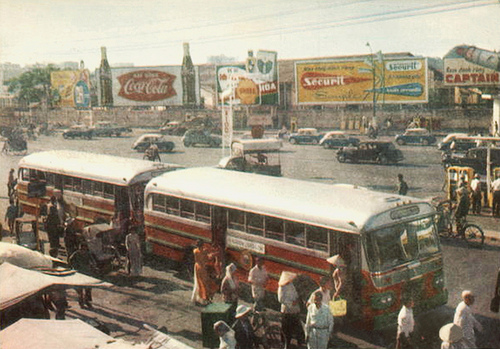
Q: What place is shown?
A: It is a parking lot.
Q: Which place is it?
A: It is a parking lot.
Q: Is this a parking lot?
A: Yes, it is a parking lot.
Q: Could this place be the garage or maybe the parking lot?
A: It is the parking lot.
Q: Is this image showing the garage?
A: No, the picture is showing the parking lot.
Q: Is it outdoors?
A: Yes, it is outdoors.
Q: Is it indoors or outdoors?
A: It is outdoors.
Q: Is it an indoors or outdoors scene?
A: It is outdoors.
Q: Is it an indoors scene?
A: No, it is outdoors.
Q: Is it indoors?
A: No, it is outdoors.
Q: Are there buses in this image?
A: Yes, there is a bus.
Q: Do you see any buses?
A: Yes, there is a bus.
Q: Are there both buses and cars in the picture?
A: Yes, there are both a bus and a car.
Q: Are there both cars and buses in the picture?
A: Yes, there are both a bus and a car.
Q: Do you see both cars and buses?
A: Yes, there are both a bus and a car.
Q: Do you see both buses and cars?
A: Yes, there are both a bus and a car.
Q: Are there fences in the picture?
A: No, there are no fences.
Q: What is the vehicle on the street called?
A: The vehicle is a bus.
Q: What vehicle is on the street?
A: The vehicle is a bus.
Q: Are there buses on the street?
A: Yes, there is a bus on the street.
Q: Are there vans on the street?
A: No, there is a bus on the street.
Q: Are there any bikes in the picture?
A: Yes, there is a bike.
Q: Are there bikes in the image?
A: Yes, there is a bike.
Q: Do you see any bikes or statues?
A: Yes, there is a bike.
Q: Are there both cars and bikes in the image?
A: Yes, there are both a bike and a car.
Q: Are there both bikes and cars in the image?
A: Yes, there are both a bike and a car.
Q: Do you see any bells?
A: No, there are no bells.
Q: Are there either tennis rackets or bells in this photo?
A: No, there are no bells or tennis rackets.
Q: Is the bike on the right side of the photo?
A: Yes, the bike is on the right of the image.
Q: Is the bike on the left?
A: No, the bike is on the right of the image.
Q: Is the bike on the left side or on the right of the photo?
A: The bike is on the right of the image.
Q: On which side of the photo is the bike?
A: The bike is on the right of the image.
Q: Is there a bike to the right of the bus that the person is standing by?
A: Yes, there is a bike to the right of the bus.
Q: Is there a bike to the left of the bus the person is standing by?
A: No, the bike is to the right of the bus.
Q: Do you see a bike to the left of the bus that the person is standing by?
A: No, the bike is to the right of the bus.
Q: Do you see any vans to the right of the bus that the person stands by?
A: No, there is a bike to the right of the bus.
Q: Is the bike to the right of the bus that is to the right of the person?
A: Yes, the bike is to the right of the bus.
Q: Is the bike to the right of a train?
A: No, the bike is to the right of the bus.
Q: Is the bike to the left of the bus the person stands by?
A: No, the bike is to the right of the bus.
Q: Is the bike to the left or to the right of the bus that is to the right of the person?
A: The bike is to the right of the bus.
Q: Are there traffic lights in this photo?
A: No, there are no traffic lights.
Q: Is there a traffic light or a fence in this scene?
A: No, there are no traffic lights or fences.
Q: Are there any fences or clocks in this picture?
A: No, there are no fences or clocks.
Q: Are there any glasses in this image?
A: No, there are no glasses.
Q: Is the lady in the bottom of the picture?
A: Yes, the lady is in the bottom of the image.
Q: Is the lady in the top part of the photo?
A: No, the lady is in the bottom of the image.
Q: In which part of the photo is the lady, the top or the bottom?
A: The lady is in the bottom of the image.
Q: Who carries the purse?
A: The lady carries the purse.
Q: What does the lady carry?
A: The lady carries a purse.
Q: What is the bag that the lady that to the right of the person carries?
A: The bag is a purse.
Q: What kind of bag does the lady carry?
A: The lady carries a purse.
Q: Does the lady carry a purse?
A: Yes, the lady carries a purse.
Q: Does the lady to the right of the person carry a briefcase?
A: No, the lady carries a purse.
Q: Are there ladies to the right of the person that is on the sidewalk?
A: Yes, there is a lady to the right of the person.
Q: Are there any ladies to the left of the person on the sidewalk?
A: No, the lady is to the right of the person.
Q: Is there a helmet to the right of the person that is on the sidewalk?
A: No, there is a lady to the right of the person.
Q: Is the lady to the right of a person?
A: Yes, the lady is to the right of a person.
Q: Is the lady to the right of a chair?
A: No, the lady is to the right of a person.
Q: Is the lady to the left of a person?
A: No, the lady is to the right of a person.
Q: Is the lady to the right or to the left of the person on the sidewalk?
A: The lady is to the right of the person.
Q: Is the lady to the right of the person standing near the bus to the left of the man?
A: Yes, the lady is standing near the bus.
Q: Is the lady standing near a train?
A: No, the lady is standing near the bus.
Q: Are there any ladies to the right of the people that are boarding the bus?
A: Yes, there is a lady to the right of the people.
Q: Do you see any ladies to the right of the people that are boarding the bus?
A: Yes, there is a lady to the right of the people.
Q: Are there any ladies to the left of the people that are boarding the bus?
A: No, the lady is to the right of the people.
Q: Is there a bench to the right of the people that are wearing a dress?
A: No, there is a lady to the right of the people.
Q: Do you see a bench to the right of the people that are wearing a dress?
A: No, there is a lady to the right of the people.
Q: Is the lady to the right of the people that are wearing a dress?
A: Yes, the lady is to the right of the people.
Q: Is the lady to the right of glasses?
A: No, the lady is to the right of the people.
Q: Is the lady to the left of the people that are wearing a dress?
A: No, the lady is to the right of the people.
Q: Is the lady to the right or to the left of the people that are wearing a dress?
A: The lady is to the right of the people.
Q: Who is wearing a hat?
A: The lady is wearing a hat.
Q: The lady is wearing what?
A: The lady is wearing a hat.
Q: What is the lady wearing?
A: The lady is wearing a hat.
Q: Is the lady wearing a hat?
A: Yes, the lady is wearing a hat.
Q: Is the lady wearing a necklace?
A: No, the lady is wearing a hat.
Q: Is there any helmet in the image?
A: No, there are no helmets.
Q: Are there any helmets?
A: No, there are no helmets.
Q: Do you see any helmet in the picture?
A: No, there are no helmets.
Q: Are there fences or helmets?
A: No, there are no helmets or fences.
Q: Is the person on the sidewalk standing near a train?
A: No, the person is standing near the bus.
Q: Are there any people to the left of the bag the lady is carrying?
A: Yes, there is a person to the left of the purse.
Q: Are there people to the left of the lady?
A: Yes, there is a person to the left of the lady.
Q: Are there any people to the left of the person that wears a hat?
A: Yes, there is a person to the left of the lady.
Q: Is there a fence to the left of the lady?
A: No, there is a person to the left of the lady.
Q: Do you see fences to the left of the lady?
A: No, there is a person to the left of the lady.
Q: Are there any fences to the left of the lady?
A: No, there is a person to the left of the lady.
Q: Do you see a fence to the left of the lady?
A: No, there is a person to the left of the lady.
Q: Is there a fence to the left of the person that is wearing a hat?
A: No, there is a person to the left of the lady.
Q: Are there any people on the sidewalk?
A: Yes, there is a person on the sidewalk.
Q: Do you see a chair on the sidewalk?
A: No, there is a person on the sidewalk.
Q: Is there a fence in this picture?
A: No, there are no fences.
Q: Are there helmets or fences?
A: No, there are no fences or helmets.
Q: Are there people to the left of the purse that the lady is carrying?
A: Yes, there is a person to the left of the purse.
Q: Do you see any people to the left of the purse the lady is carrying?
A: Yes, there is a person to the left of the purse.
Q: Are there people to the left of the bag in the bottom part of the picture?
A: Yes, there is a person to the left of the purse.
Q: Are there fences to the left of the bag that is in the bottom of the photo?
A: No, there is a person to the left of the purse.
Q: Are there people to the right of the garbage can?
A: Yes, there is a person to the right of the garbage can.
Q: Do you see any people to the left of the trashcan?
A: No, the person is to the right of the trashcan.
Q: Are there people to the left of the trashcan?
A: No, the person is to the right of the trashcan.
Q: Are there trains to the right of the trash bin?
A: No, there is a person to the right of the trash bin.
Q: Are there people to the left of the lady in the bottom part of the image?
A: Yes, there is a person to the left of the lady.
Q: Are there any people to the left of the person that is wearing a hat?
A: Yes, there is a person to the left of the lady.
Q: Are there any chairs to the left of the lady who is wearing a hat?
A: No, there is a person to the left of the lady.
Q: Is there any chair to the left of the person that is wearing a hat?
A: No, there is a person to the left of the lady.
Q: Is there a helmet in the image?
A: No, there are no helmets.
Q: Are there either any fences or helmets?
A: No, there are no helmets or fences.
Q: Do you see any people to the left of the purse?
A: Yes, there is a person to the left of the purse.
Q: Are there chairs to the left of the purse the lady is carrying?
A: No, there is a person to the left of the purse.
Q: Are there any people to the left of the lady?
A: Yes, there is a person to the left of the lady.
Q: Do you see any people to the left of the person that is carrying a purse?
A: Yes, there is a person to the left of the lady.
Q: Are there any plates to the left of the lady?
A: No, there is a person to the left of the lady.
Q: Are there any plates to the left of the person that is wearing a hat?
A: No, there is a person to the left of the lady.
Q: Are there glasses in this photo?
A: No, there are no glasses.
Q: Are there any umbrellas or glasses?
A: No, there are no glasses or umbrellas.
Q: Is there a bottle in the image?
A: Yes, there is a bottle.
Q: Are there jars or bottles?
A: Yes, there is a bottle.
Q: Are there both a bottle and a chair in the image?
A: No, there is a bottle but no chairs.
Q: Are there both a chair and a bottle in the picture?
A: No, there is a bottle but no chairs.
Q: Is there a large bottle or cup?
A: Yes, there is a large bottle.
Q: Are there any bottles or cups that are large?
A: Yes, the bottle is large.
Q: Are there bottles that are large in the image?
A: Yes, there is a large bottle.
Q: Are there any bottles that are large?
A: Yes, there is a bottle that is large.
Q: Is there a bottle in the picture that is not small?
A: Yes, there is a large bottle.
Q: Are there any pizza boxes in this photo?
A: No, there are no pizza boxes.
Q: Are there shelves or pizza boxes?
A: No, there are no pizza boxes or shelves.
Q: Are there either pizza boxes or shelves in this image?
A: No, there are no pizza boxes or shelves.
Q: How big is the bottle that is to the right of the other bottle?
A: The bottle is large.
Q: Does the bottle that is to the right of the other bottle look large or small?
A: The bottle is large.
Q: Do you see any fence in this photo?
A: No, there are no fences.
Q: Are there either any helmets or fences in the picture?
A: No, there are no fences or helmets.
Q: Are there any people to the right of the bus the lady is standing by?
A: Yes, there is a person to the right of the bus.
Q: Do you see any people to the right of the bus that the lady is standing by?
A: Yes, there is a person to the right of the bus.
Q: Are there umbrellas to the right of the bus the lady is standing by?
A: No, there is a person to the right of the bus.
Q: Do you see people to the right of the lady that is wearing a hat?
A: Yes, there is a person to the right of the lady.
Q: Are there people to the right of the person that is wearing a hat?
A: Yes, there is a person to the right of the lady.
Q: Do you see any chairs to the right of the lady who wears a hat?
A: No, there is a person to the right of the lady.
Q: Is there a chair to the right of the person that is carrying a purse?
A: No, there is a person to the right of the lady.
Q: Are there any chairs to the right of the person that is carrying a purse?
A: No, there is a person to the right of the lady.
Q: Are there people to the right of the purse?
A: Yes, there is a person to the right of the purse.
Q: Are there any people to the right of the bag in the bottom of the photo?
A: Yes, there is a person to the right of the purse.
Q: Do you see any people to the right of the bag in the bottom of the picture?
A: Yes, there is a person to the right of the purse.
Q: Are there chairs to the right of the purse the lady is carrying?
A: No, there is a person to the right of the purse.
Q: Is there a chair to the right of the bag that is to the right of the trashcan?
A: No, there is a person to the right of the purse.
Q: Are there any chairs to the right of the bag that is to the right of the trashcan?
A: No, there is a person to the right of the purse.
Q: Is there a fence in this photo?
A: No, there are no fences.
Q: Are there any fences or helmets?
A: No, there are no fences or helmets.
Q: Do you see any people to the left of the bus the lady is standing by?
A: Yes, there is a person to the left of the bus.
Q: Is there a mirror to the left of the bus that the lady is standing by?
A: No, there is a person to the left of the bus.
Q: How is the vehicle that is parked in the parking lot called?
A: The vehicle is a car.